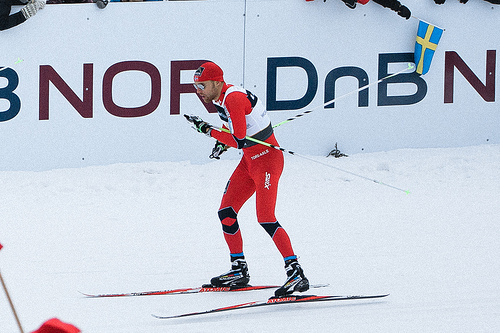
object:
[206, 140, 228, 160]
gloves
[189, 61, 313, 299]
uniform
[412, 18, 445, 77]
flag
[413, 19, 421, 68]
edge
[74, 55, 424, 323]
skier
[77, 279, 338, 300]
ski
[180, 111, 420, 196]
ski pole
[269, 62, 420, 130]
ski pole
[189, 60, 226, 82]
hat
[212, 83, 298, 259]
snowsuit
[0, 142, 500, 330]
snow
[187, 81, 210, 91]
sunglasses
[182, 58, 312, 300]
man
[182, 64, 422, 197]
sticks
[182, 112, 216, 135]
gloves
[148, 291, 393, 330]
ski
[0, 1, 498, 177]
wall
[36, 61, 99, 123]
letters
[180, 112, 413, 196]
outfit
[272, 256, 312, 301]
boot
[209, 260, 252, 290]
boot